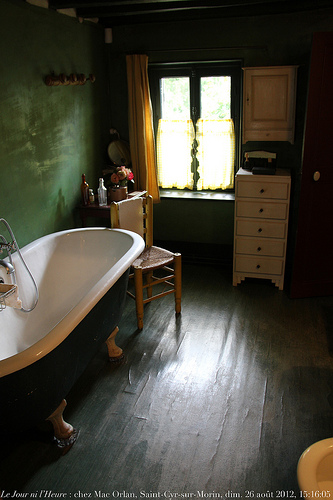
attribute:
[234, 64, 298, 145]
cabinet — wooden, white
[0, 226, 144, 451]
tub — white, standalone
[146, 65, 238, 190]
window — covered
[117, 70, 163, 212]
curtain — yellow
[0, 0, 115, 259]
wall — green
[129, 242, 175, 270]
seat — wicker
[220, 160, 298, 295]
drawer — white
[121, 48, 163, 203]
yellow curtain — long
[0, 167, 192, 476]
tub — bath tub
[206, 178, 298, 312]
cabinet — wooden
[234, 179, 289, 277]
drawers — white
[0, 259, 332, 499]
floor — old, hardwood, wooden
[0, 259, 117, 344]
tub — black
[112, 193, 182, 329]
chair — wooden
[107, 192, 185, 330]
chair — brown, wicker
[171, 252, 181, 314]
leg — four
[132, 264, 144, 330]
leg — four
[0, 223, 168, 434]
bathtub — long, traditional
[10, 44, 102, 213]
exterior — green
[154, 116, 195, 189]
curtain — yellow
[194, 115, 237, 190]
curtain — yellow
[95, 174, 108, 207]
bottle — empty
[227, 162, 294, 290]
chest — white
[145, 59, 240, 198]
window — small